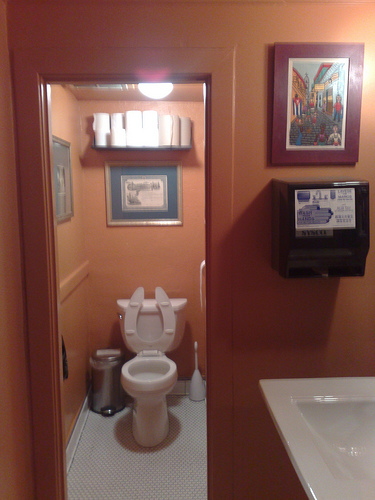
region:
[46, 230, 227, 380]
this is a bathroom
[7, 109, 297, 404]
it is an indoor scene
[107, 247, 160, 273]
the wall is orange in color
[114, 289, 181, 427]
the toilet is white in color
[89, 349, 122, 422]
the trash can is silver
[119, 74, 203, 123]
the light is on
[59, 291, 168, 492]
the bathroom is clean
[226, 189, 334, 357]
a shadow is cast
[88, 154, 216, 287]
there are pictures on the wall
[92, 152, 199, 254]
the picture is framed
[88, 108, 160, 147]
large amount of toilet paper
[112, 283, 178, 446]
toilet seat left open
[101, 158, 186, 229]
picture on bathroom wall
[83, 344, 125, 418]
stainless steel trash can with lid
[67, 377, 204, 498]
grey tile floor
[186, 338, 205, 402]
white toilet scrubber with cover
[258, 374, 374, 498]
white porcelain sink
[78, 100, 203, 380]
orange colored wall in bathroom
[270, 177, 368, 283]
black paper towel holder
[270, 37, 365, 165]
picture hanging above sink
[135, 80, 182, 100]
light illuminates the bathroom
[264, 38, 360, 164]
a painting hanging on the wall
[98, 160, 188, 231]
a plaque hangs above the toilet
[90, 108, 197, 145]
several rolls of toilet paper on a shelf above the toilet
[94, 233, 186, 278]
wall is painted orange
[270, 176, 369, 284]
paper towel dispenser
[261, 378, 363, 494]
part of a porcelain vanity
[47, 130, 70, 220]
a picture hangs on the wall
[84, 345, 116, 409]
metal wastepaper basket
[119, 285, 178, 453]
white porcelain toilet bowl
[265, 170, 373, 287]
paper towel dispenser on the wall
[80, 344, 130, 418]
stainless steel trash can in bathroom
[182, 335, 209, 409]
a white toilet brush set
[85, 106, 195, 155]
rolls of toilet paper and paper towels on a shelf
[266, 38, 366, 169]
framed art mounted on wall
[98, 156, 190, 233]
framed wall art above toilet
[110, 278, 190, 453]
a very clean-looking toilet bowl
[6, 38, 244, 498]
well-lit and clean restroom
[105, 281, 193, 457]
white toilet with the toilet seat up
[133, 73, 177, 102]
light turned on in the restroom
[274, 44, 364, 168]
a picture is hanging on a wall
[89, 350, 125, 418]
a metal waste paper basket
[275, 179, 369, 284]
black paper towel dispenser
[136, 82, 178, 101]
light hanging from the ceiling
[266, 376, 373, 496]
white bathroom sink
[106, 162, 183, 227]
plaque is hanging on a wall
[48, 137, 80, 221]
picture is hanging from a wall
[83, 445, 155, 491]
floor has white tiling